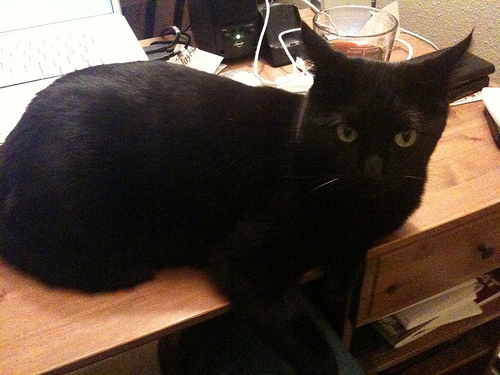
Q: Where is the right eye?
A: On the cat.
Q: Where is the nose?
A: On the cat.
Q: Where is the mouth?
A: On the cat.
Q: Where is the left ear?
A: On the cat.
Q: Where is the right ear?
A: On the cat.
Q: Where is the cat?
A: On the table.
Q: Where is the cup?
A: On the table.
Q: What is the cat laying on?
A: Wooden desk.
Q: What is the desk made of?
A: Wood.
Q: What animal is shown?
A: Cat.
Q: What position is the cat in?
A: Laying down.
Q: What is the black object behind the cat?
A: Speaker.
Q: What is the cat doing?
A: Laying down.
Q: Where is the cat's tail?
A: Curled up.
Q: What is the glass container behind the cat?
A: Candle.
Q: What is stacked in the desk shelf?
A: Papers.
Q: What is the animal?
A: Cat.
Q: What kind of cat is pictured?
A: Black.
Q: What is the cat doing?
A: Lying down.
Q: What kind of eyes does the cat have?
A: Yellow.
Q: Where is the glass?
A: Behind cat.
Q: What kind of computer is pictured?
A: Laptop.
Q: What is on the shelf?
A: Papers.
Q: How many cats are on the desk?
A: One.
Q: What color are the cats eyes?
A: Yellow.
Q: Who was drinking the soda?
A: The owner of the cat.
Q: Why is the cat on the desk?
A: Its comfortable.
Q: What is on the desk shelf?
A: Mail.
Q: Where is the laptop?
A: On the desk.